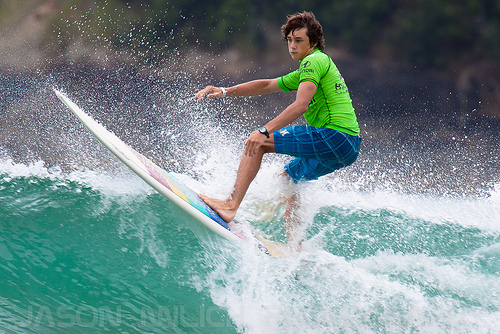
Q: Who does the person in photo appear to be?
A: Teenage boy.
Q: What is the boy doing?
A: Surfing.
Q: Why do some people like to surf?
A: For excitement.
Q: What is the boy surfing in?
A: Ocean.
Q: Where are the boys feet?
A: On surfboard.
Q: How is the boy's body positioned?
A: Bent.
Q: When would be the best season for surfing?
A: Summertime.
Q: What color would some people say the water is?
A: Aqua marine.